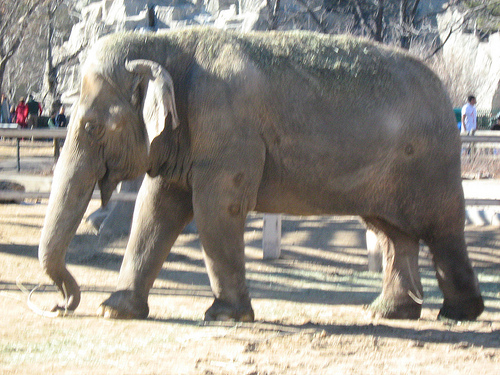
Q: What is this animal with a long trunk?
A: Elephant.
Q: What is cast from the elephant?
A: Shadow.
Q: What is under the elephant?
A: Dirt.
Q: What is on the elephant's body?
A: Hair.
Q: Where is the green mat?
A: Elephants back.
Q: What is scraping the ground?
A: Elephants trunk.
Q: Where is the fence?
A: Behind elephant.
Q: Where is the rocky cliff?
A: Behind elephant.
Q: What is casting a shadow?
A: Elephant.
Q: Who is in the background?
A: Man in white shirt.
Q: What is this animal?
A: An elephant.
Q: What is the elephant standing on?
A: Legs.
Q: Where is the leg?
A: In front.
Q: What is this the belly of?
A: An elephant.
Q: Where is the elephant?
A: At a zoo.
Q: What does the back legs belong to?
A: An elephant.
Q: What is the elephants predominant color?
A: Grey.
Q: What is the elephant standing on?
A: Dirt.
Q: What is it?
A: Elephant.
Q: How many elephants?
A: 1.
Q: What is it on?
A: Dirt.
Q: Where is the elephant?
A: Zoo.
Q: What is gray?
A: Elephant.